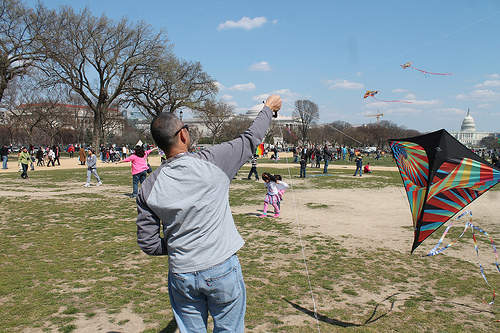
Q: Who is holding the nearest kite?
A: Man in jeans.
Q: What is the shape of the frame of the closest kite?
A: A cross.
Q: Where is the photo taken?
A: Washington DC.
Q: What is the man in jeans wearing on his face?
A: Glasses.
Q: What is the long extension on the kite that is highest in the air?
A: Tail.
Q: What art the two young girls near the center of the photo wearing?
A: Skirts.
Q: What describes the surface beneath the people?
A: Grass and dirt.